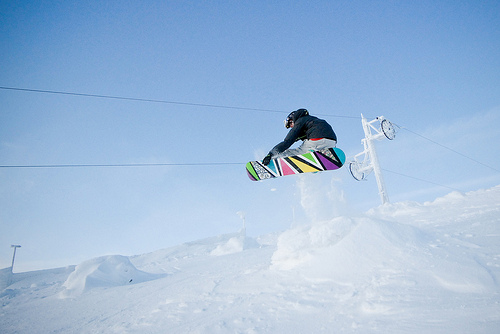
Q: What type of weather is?
A: It is clear.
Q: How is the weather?
A: It is clear.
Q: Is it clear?
A: Yes, it is clear.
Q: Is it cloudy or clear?
A: It is clear.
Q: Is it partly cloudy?
A: No, it is clear.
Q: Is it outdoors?
A: Yes, it is outdoors.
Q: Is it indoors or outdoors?
A: It is outdoors.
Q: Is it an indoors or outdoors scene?
A: It is outdoors.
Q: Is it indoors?
A: No, it is outdoors.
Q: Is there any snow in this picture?
A: Yes, there is snow.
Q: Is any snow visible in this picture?
A: Yes, there is snow.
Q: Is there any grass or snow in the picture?
A: Yes, there is snow.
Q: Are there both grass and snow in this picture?
A: No, there is snow but no grass.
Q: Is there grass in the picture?
A: No, there is no grass.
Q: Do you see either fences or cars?
A: No, there are no fences or cars.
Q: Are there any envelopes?
A: No, there are no envelopes.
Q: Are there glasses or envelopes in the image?
A: No, there are no envelopes or glasses.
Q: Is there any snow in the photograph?
A: Yes, there is snow.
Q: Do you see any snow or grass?
A: Yes, there is snow.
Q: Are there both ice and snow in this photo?
A: No, there is snow but no ice.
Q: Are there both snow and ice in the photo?
A: No, there is snow but no ice.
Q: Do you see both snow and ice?
A: No, there is snow but no ice.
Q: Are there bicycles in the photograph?
A: No, there are no bicycles.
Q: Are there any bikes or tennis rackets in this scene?
A: No, there are no bikes or tennis rackets.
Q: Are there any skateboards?
A: No, there are no skateboards.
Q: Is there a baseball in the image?
A: No, there are no baseballs.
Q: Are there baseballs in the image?
A: No, there are no baseballs.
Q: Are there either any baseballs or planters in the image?
A: No, there are no baseballs or planters.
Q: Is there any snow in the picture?
A: Yes, there is snow.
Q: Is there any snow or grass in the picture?
A: Yes, there is snow.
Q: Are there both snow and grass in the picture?
A: No, there is snow but no grass.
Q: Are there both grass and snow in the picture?
A: No, there is snow but no grass.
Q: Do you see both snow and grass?
A: No, there is snow but no grass.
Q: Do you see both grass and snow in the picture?
A: No, there is snow but no grass.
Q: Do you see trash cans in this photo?
A: No, there are no trash cans.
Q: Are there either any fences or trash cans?
A: No, there are no trash cans or fences.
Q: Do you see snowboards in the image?
A: Yes, there is a snowboard.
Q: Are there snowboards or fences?
A: Yes, there is a snowboard.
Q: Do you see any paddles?
A: No, there are no paddles.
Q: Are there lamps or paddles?
A: No, there are no paddles or lamps.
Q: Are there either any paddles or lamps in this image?
A: No, there are no paddles or lamps.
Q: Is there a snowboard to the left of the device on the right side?
A: Yes, there is a snowboard to the left of the device.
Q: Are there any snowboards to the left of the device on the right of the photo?
A: Yes, there is a snowboard to the left of the device.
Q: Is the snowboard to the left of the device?
A: Yes, the snowboard is to the left of the device.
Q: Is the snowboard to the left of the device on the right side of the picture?
A: Yes, the snowboard is to the left of the device.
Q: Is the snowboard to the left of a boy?
A: No, the snowboard is to the left of the device.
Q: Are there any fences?
A: No, there are no fences.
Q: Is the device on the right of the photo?
A: Yes, the device is on the right of the image.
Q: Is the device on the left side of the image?
A: No, the device is on the right of the image.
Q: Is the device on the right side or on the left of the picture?
A: The device is on the right of the image.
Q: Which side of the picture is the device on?
A: The device is on the right of the image.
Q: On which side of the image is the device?
A: The device is on the right of the image.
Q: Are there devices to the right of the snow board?
A: Yes, there is a device to the right of the snow board.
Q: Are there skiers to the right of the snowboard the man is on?
A: No, there is a device to the right of the snowboard.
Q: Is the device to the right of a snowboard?
A: Yes, the device is to the right of a snowboard.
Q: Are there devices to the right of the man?
A: Yes, there is a device to the right of the man.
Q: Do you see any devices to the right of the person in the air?
A: Yes, there is a device to the right of the man.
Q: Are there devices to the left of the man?
A: No, the device is to the right of the man.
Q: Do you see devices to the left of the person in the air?
A: No, the device is to the right of the man.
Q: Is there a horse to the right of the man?
A: No, there is a device to the right of the man.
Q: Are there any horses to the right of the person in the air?
A: No, there is a device to the right of the man.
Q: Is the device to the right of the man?
A: Yes, the device is to the right of the man.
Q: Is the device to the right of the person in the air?
A: Yes, the device is to the right of the man.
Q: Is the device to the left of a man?
A: No, the device is to the right of a man.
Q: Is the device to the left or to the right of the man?
A: The device is to the right of the man.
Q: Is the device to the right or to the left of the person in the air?
A: The device is to the right of the man.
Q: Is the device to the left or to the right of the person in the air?
A: The device is to the right of the man.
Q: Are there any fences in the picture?
A: No, there are no fences.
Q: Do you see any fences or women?
A: No, there are no fences or women.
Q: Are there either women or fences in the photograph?
A: No, there are no fences or women.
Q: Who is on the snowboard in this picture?
A: The man is on the snowboard.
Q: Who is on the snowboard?
A: The man is on the snowboard.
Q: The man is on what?
A: The man is on the snowboard.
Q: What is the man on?
A: The man is on the snowboard.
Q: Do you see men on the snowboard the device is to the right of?
A: Yes, there is a man on the snow board.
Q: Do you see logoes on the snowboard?
A: No, there is a man on the snowboard.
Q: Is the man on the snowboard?
A: Yes, the man is on the snowboard.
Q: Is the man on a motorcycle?
A: No, the man is on the snowboard.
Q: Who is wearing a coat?
A: The man is wearing a coat.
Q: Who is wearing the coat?
A: The man is wearing a coat.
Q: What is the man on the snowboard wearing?
A: The man is wearing a coat.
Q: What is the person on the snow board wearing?
A: The man is wearing a coat.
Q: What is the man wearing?
A: The man is wearing a coat.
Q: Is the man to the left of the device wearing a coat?
A: Yes, the man is wearing a coat.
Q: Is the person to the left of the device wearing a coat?
A: Yes, the man is wearing a coat.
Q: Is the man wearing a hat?
A: No, the man is wearing a coat.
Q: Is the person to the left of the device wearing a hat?
A: No, the man is wearing a coat.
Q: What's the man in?
A: The man is in the air.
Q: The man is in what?
A: The man is in the air.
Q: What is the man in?
A: The man is in the air.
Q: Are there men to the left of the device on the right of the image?
A: Yes, there is a man to the left of the device.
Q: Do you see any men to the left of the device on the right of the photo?
A: Yes, there is a man to the left of the device.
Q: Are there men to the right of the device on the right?
A: No, the man is to the left of the device.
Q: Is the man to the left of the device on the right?
A: Yes, the man is to the left of the device.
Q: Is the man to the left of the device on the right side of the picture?
A: Yes, the man is to the left of the device.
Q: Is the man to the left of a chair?
A: No, the man is to the left of the device.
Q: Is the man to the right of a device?
A: No, the man is to the left of a device.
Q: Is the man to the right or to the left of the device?
A: The man is to the left of the device.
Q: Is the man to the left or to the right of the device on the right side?
A: The man is to the left of the device.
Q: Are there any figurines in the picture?
A: No, there are no figurines.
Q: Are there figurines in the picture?
A: No, there are no figurines.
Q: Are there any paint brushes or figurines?
A: No, there are no figurines or paint brushes.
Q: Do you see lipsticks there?
A: No, there are no lipsticks.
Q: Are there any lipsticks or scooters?
A: No, there are no lipsticks or scooters.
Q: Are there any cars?
A: No, there are no cars.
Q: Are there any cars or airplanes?
A: No, there are no cars or airplanes.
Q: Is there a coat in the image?
A: Yes, there is a coat.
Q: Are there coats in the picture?
A: Yes, there is a coat.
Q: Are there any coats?
A: Yes, there is a coat.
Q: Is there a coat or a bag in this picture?
A: Yes, there is a coat.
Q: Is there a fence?
A: No, there are no fences.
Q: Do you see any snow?
A: Yes, there is snow.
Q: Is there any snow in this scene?
A: Yes, there is snow.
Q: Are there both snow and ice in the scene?
A: No, there is snow but no ice.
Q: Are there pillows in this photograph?
A: No, there are no pillows.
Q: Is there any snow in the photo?
A: Yes, there is snow.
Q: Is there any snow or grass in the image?
A: Yes, there is snow.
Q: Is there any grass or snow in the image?
A: Yes, there is snow.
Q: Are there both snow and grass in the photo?
A: No, there is snow but no grass.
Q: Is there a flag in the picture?
A: No, there are no flags.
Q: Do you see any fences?
A: No, there are no fences.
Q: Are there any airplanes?
A: No, there are no airplanes.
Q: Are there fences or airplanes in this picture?
A: No, there are no airplanes or fences.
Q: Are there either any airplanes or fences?
A: No, there are no airplanes or fences.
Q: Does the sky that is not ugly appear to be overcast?
A: No, the sky is clear.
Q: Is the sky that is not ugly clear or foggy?
A: The sky is clear.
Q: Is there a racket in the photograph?
A: No, there are no rackets.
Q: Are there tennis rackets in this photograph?
A: No, there are no tennis rackets.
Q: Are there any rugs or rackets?
A: No, there are no rackets or rugs.